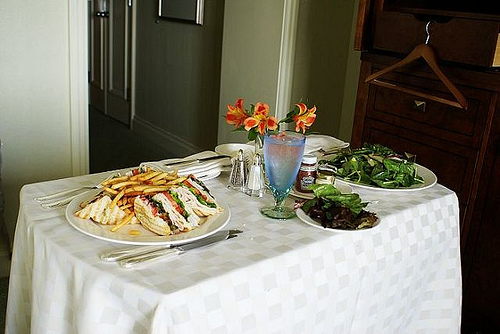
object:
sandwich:
[133, 193, 185, 236]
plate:
[64, 182, 231, 247]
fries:
[110, 181, 143, 189]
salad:
[354, 152, 402, 176]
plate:
[316, 152, 438, 193]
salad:
[320, 194, 350, 209]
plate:
[295, 201, 383, 233]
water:
[263, 135, 306, 192]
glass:
[259, 131, 308, 221]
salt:
[247, 164, 267, 191]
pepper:
[228, 159, 249, 188]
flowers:
[243, 101, 278, 135]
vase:
[254, 134, 273, 194]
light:
[279, 148, 286, 157]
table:
[20, 135, 458, 300]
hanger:
[362, 18, 476, 117]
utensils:
[33, 173, 120, 204]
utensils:
[97, 229, 245, 263]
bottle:
[296, 154, 318, 194]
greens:
[346, 157, 363, 183]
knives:
[119, 234, 239, 269]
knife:
[163, 155, 232, 168]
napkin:
[138, 154, 234, 182]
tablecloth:
[5, 137, 463, 334]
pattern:
[386, 225, 419, 261]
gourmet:
[109, 168, 168, 202]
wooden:
[364, 43, 473, 118]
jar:
[296, 154, 318, 194]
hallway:
[85, 0, 224, 175]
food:
[71, 164, 226, 238]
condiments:
[295, 155, 318, 194]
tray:
[285, 180, 355, 201]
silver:
[95, 11, 109, 18]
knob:
[95, 11, 110, 19]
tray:
[63, 184, 232, 246]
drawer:
[369, 9, 499, 72]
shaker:
[224, 149, 249, 193]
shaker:
[240, 154, 268, 198]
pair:
[99, 229, 246, 270]